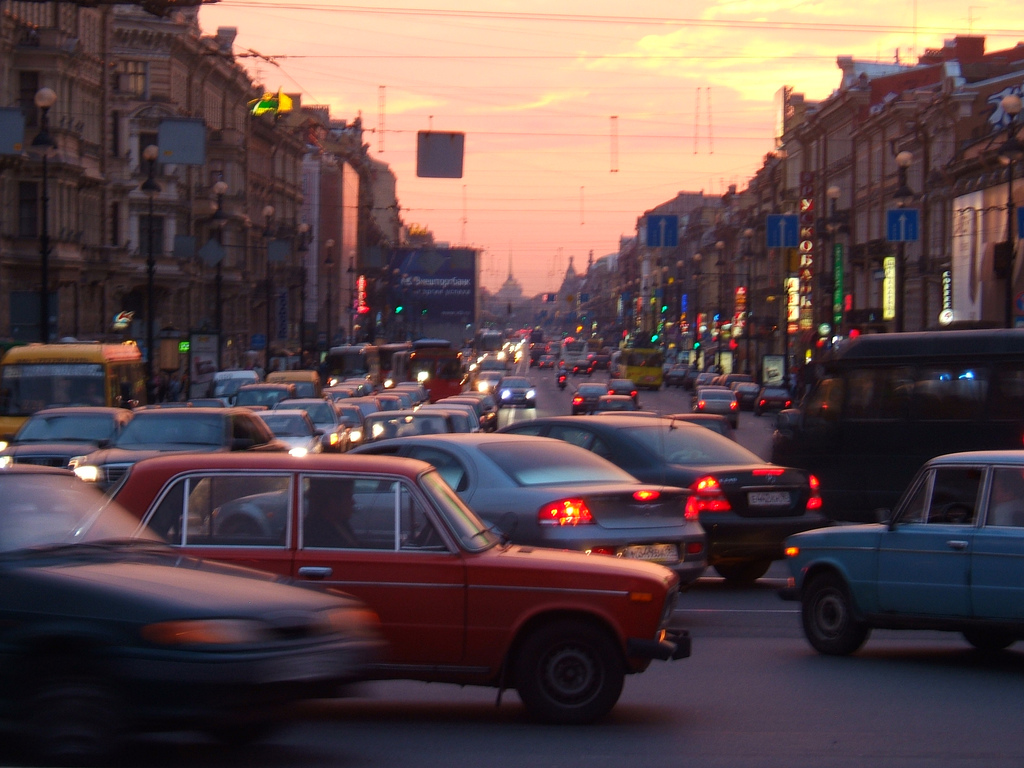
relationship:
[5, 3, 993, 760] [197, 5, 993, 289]
scene happening during sunset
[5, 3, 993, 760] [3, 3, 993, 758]
scene happening during outside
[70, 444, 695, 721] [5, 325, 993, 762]
vehicle moving on road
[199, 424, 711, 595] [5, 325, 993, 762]
vehicle moving on road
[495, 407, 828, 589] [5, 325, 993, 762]
vehicle moving on road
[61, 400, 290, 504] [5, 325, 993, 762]
vehicle moving on road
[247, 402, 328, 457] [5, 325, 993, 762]
vehicle moving on road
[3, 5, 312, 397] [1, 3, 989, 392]
building standing in background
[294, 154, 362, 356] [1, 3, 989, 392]
building standing in background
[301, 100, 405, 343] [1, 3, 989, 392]
building standing in background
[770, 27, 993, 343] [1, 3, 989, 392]
building standing in background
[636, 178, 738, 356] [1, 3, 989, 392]
building standing in background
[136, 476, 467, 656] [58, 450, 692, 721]
doors on a sedan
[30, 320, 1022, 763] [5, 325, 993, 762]
cars on a road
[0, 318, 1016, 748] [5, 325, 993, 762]
traffic on a road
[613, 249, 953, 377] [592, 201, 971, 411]
lights on stores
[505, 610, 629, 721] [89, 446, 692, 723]
tire on car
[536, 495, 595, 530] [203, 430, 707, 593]
tail light on car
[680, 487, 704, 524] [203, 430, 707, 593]
tail light on car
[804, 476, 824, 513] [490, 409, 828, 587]
tail light on car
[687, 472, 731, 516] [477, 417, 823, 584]
tail light on car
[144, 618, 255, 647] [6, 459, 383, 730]
light on car